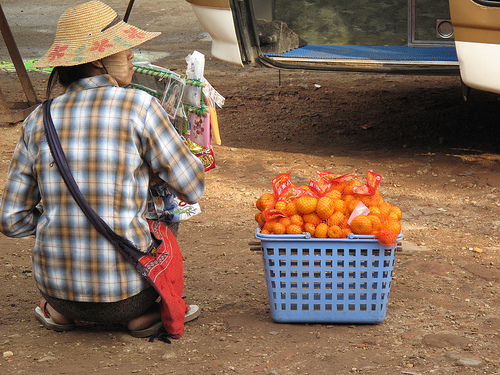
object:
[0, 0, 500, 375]
ground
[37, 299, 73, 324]
foot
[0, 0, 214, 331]
woman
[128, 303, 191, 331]
foot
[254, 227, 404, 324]
basket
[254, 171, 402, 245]
oranges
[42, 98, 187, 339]
bag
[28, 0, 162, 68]
hat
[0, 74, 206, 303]
shirt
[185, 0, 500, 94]
van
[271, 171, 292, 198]
bag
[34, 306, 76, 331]
flip-flops